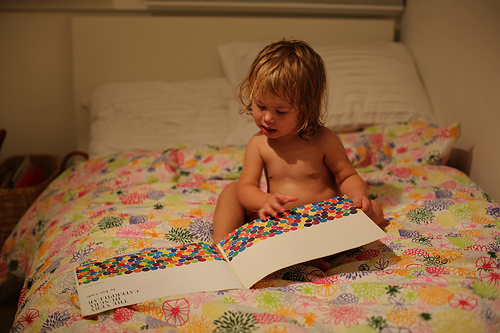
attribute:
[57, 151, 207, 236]
comforter — colorful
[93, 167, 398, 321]
bedspread — colorful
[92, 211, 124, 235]
flower — red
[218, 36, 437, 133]
pillows — white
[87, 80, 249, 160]
pillows — white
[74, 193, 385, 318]
book — open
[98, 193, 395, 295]
book — colorful, open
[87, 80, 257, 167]
pillow — striped, white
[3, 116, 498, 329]
bed spread — colorfull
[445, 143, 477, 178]
shadow — small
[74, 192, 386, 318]
children's book — large, colorfull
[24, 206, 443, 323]
book — open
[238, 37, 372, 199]
child — small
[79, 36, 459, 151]
pillows — white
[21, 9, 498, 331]
bed — colored, colorful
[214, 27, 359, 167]
hair — blond, messy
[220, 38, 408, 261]
child — small, blond, naked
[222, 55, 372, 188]
child — small, blond, naked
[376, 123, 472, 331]
bedspread — colorful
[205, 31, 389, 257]
child — naked, blond, small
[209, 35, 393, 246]
child — small, blond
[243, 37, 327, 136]
hair — light brown